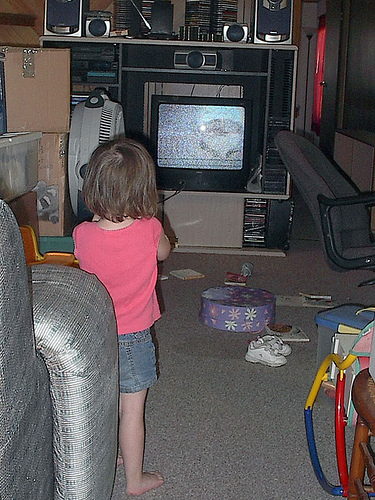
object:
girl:
[72, 134, 173, 499]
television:
[148, 95, 254, 191]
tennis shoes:
[243, 340, 286, 368]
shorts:
[117, 327, 161, 393]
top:
[72, 217, 163, 332]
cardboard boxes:
[5, 44, 70, 135]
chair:
[273, 130, 374, 271]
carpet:
[111, 184, 374, 499]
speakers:
[252, 1, 294, 46]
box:
[200, 283, 276, 335]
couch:
[2, 197, 119, 499]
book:
[267, 321, 309, 345]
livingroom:
[0, 2, 373, 499]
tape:
[24, 50, 36, 77]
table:
[10, 191, 42, 255]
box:
[2, 130, 43, 202]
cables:
[159, 178, 183, 206]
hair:
[84, 138, 161, 224]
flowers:
[224, 319, 236, 331]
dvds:
[241, 227, 265, 241]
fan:
[67, 86, 124, 222]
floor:
[111, 183, 374, 499]